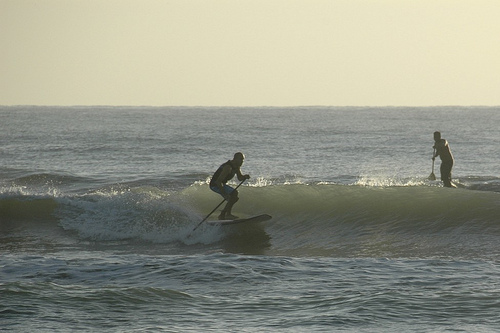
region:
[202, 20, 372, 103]
the sky is yellow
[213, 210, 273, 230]
surfboard in the water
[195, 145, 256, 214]
surfer in the water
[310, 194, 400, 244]
the wave is green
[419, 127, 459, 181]
man in the water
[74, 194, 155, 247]
waves in the water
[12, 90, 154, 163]
sky on the horizon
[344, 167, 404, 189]
white curl on waves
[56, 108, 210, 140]
the water is calm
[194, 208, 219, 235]
paddle in the ocean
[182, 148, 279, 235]
Person balancing on a surfboard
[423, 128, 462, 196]
Person holding an object in the water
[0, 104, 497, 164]
Gentle portion of the water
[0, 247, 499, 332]
Gentle water in the foreground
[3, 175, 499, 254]
Rough advancing wave front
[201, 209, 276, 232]
Feet on the surfboard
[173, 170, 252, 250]
Hands holding a long object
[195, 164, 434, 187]
Water splashing in the air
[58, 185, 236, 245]
Splash trail left by the surfboard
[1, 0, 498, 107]
Clear skyline in the background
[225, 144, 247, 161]
head of a person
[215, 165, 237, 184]
arm of a person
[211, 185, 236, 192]
hand of a person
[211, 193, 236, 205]
leg of a person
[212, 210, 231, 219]
feet of a person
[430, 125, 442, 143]
head of a person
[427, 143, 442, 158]
arm of a person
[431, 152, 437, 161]
hand of a person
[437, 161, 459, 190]
leg of a person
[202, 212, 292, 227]
surb board on water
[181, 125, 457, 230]
two people on water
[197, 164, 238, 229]
man is holding paddle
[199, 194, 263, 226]
man on white board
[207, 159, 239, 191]
man has black jacket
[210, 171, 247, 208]
man has blue shorts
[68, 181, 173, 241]
white wave near man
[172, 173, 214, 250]
small wake from board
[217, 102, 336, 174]
water is dark blue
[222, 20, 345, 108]
white and yellow sky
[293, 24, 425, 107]
early morning color in sky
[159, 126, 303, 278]
a surfer with paddle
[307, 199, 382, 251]
the water is murky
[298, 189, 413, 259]
the water is murky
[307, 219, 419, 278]
the water is murky